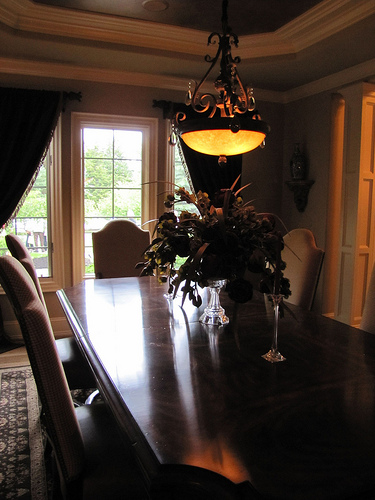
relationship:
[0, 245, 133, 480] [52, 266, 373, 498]
chair around table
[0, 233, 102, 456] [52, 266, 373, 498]
chairs around table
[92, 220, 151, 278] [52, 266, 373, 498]
chair around table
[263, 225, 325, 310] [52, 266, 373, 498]
chairs around table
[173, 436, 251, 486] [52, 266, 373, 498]
light on table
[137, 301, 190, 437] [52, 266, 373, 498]
shadow on table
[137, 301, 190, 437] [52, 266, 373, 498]
shadow falling on table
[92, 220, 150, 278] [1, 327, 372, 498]
chair on ground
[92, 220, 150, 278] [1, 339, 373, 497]
chair on floor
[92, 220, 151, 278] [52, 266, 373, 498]
chair near table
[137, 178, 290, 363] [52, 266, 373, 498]
flower on table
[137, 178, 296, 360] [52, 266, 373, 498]
flower on table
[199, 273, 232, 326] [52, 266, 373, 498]
vase on table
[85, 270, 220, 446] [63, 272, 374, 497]
reflection on desk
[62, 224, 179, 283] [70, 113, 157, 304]
pink chair and window